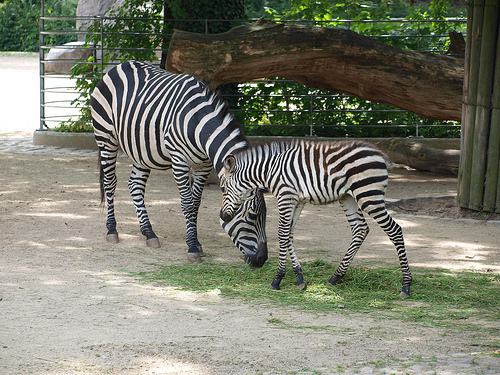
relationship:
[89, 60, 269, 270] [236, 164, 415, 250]
adult zebra zebras have stripes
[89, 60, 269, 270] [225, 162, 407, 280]
adult zebra are black and white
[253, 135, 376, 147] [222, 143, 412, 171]
short mane on zebras back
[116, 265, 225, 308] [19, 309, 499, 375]
patch of light amid shadows on ground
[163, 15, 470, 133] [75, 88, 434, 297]
large wooden branch behind zebras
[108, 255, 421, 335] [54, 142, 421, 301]
patch of grass beneath zebras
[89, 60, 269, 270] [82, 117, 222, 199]
adult zebra an adult zebra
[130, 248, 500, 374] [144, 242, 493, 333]
grass on ground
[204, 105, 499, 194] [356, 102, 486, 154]
large log on ground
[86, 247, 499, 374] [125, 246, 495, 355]
grass area a grass area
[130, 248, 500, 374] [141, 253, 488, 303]
grass in color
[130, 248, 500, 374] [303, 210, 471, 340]
grass leaves are green in color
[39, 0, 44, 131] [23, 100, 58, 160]
pole a pole